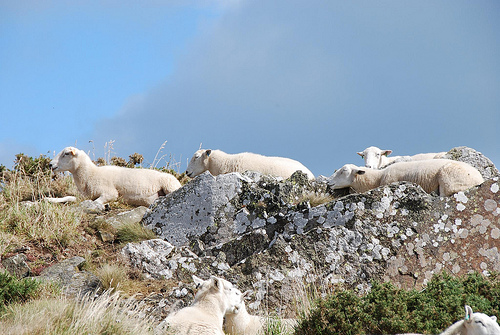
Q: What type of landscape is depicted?
A: Rocky; dry grass.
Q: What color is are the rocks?
A: Gray, white and brownish-red.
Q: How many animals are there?
A: 7.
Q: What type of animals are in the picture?
A: Sheep.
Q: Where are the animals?
A: Outside on a rocky landscape.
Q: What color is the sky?
A: Blue.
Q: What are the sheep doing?
A: Walking and interacting with each other.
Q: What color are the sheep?
A: White.